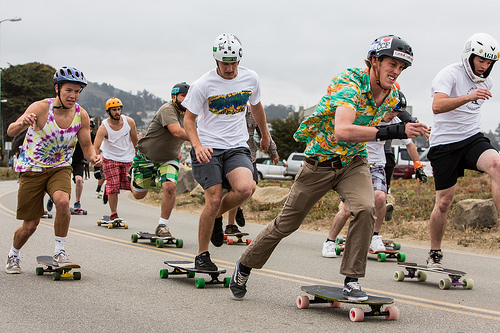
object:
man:
[8, 63, 104, 275]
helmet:
[52, 65, 90, 87]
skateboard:
[294, 282, 402, 324]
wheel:
[295, 294, 313, 311]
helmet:
[105, 98, 122, 111]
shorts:
[101, 157, 135, 195]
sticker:
[374, 36, 393, 50]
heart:
[383, 37, 391, 41]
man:
[230, 27, 428, 302]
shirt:
[292, 66, 401, 166]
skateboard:
[222, 231, 253, 246]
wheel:
[226, 236, 235, 247]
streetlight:
[0, 15, 25, 24]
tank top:
[12, 96, 81, 171]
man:
[320, 78, 427, 265]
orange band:
[413, 160, 424, 171]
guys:
[5, 66, 103, 282]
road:
[1, 173, 499, 332]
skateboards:
[36, 253, 84, 281]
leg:
[465, 137, 499, 219]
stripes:
[0, 183, 500, 323]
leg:
[240, 167, 331, 270]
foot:
[195, 252, 220, 272]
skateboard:
[159, 258, 234, 290]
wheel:
[194, 277, 208, 290]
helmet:
[214, 32, 245, 61]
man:
[424, 34, 498, 271]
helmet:
[461, 29, 499, 83]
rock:
[248, 180, 295, 212]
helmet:
[170, 81, 193, 95]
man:
[127, 82, 190, 241]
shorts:
[129, 147, 179, 193]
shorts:
[427, 132, 497, 191]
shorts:
[15, 165, 74, 222]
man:
[182, 31, 274, 274]